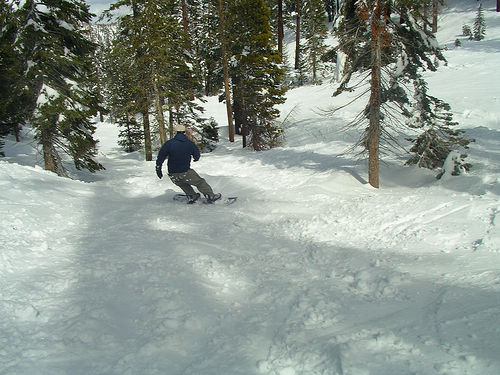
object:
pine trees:
[0, 0, 486, 188]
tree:
[308, 0, 477, 190]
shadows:
[0, 0, 499, 375]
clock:
[221, 0, 309, 150]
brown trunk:
[368, 0, 380, 188]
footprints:
[265, 216, 408, 327]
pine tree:
[462, 6, 487, 41]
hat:
[176, 124, 186, 131]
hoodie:
[156, 133, 201, 172]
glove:
[156, 166, 163, 179]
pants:
[168, 169, 215, 199]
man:
[155, 124, 220, 201]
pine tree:
[218, 0, 290, 151]